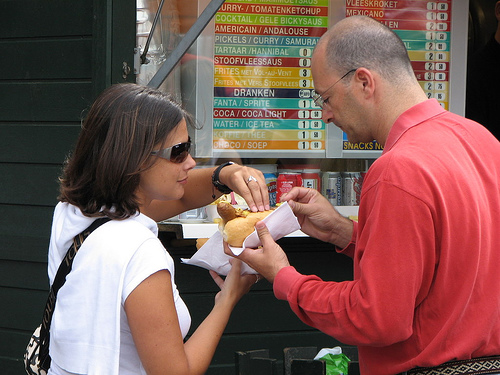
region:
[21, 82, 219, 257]
Dark hair on a woman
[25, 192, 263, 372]
White shirt on a woman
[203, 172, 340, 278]
Hot dog in a hand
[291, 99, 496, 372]
Red long sleeve shirt on a man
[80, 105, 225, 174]
Sunglasses on a woman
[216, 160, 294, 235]
Ring on a hand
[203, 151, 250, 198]
Watch on a hand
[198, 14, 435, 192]
Price sign by a couple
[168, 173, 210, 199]
Mouth on a woman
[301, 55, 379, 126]
Glasses on a man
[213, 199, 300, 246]
hot dog on a napkin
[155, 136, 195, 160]
black and gray shades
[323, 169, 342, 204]
silver can with a blue design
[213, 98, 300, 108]
white text on a aqua blue background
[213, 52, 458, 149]
menu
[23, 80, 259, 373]
woman holding a white napkin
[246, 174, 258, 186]
silver ring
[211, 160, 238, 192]
black watch with a silver buckle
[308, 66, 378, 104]
glasses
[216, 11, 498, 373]
man holding a hotdog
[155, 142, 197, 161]
Gray and black shades on woman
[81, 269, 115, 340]
White shirt of woman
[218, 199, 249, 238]
Hot dog that is about to be eaten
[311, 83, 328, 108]
Glasses of the man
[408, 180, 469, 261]
Red shirt of the man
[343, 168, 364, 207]
Gray and red soda can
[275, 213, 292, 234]
White napkin that covers hot dog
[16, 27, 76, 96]
Dark green wooden wall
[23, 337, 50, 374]
Black and white purse of woman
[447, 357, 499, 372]
Diamond style belt of man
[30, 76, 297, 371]
Woman in white shirt holding a hot dog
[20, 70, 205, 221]
Woman with dark hair and sunglasses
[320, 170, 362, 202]
Cans of soda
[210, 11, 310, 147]
Menu board and prices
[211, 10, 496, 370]
Man in red shirt holding a hot dog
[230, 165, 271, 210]
Womans hand with ring on middle finger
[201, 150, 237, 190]
Black watch on womans arm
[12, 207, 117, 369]
Black and white purse and strap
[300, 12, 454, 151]
Man with thin hair and glasses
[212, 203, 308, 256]
Hot dog with white paper underneath it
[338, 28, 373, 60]
This man appears to be rapidly balding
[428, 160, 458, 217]
This man is wearing a red, long-sleeved shirt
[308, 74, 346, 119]
This man has a pair of prescription glasses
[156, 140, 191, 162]
This woman is wearing a pair of sunglasses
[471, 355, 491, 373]
This man is wearing an intricately designed belt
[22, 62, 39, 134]
The color of this stand is a deep black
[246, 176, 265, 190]
This woman is wearing a large ring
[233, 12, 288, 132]
This seems to be the menu of a popular food place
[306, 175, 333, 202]
This place is currently serving cans of beer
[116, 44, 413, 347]
It is assumed that this season is summer